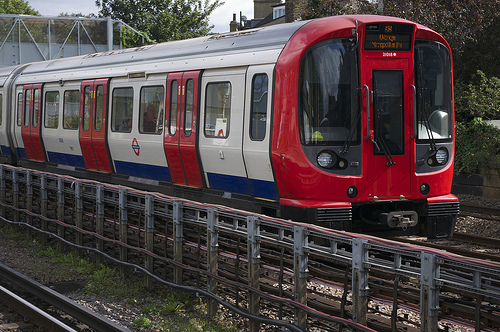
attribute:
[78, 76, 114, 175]
door — red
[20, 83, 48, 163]
door — red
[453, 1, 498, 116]
tree — green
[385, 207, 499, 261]
track — brown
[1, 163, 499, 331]
fence — silver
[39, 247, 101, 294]
grass — green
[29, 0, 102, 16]
sky — cloudy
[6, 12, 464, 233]
train — red, white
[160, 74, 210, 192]
door — red